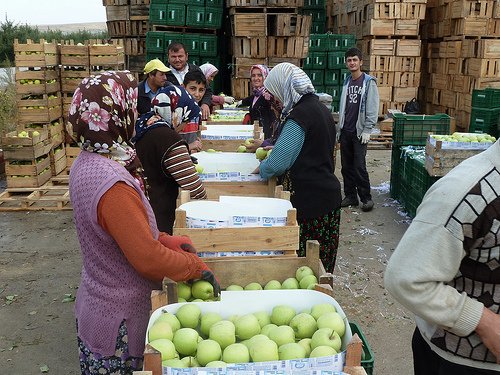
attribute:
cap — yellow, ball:
[133, 57, 169, 81]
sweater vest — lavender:
[65, 150, 157, 358]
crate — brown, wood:
[59, 146, 80, 179]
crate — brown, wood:
[89, 42, 126, 67]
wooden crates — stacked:
[184, 224, 301, 252]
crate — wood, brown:
[57, 89, 77, 124]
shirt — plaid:
[62, 178, 149, 336]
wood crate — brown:
[52, 42, 122, 55]